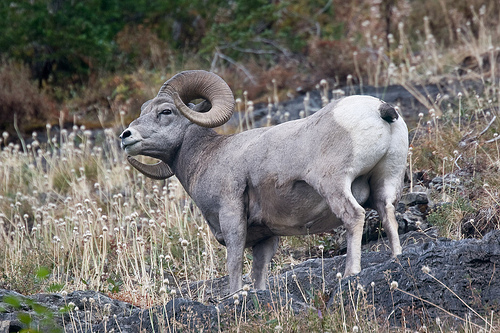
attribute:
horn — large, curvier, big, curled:
[162, 75, 243, 123]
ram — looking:
[122, 68, 431, 305]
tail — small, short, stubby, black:
[379, 101, 403, 128]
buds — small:
[42, 199, 146, 225]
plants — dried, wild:
[9, 223, 199, 307]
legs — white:
[333, 203, 414, 275]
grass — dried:
[32, 35, 499, 102]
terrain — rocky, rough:
[241, 67, 499, 144]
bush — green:
[20, 11, 147, 89]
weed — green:
[55, 238, 480, 332]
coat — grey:
[222, 147, 322, 188]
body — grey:
[249, 139, 341, 217]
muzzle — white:
[118, 139, 153, 156]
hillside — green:
[29, 34, 499, 206]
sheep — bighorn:
[125, 59, 434, 247]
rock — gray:
[444, 56, 489, 92]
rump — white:
[344, 102, 415, 180]